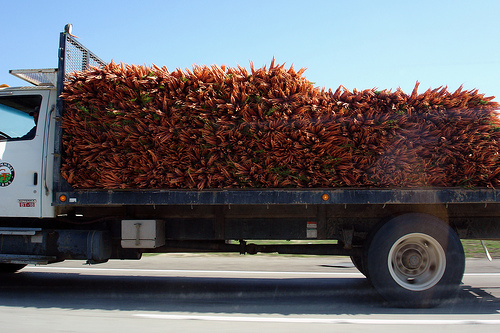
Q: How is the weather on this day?
A: It is cloudless.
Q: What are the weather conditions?
A: It is cloudless.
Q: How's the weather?
A: It is cloudless.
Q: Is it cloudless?
A: Yes, it is cloudless.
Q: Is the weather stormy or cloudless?
A: It is cloudless.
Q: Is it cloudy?
A: No, it is cloudless.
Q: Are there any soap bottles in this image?
A: No, there are no soap bottles.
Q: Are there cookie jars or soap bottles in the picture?
A: No, there are no soap bottles or cookie jars.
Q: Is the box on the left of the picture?
A: Yes, the box is on the left of the image.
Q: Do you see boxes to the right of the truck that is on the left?
A: Yes, there is a box to the right of the truck.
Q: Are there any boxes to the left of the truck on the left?
A: No, the box is to the right of the truck.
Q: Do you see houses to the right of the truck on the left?
A: No, there is a box to the right of the truck.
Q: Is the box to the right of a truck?
A: Yes, the box is to the right of a truck.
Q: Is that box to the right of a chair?
A: No, the box is to the right of a truck.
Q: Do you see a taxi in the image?
A: Yes, there is a taxi.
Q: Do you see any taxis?
A: Yes, there is a taxi.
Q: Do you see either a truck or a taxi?
A: Yes, there is a taxi.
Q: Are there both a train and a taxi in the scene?
A: No, there is a taxi but no trains.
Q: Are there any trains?
A: No, there are no trains.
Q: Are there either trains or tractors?
A: No, there are no trains or tractors.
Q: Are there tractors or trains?
A: No, there are no trains or tractors.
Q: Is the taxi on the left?
A: Yes, the taxi is on the left of the image.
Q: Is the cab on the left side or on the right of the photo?
A: The cab is on the left of the image.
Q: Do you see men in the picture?
A: No, there are no men.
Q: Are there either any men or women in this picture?
A: No, there are no men or women.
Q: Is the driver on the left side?
A: Yes, the driver is on the left of the image.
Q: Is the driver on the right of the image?
A: No, the driver is on the left of the image.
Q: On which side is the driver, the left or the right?
A: The driver is on the left of the image.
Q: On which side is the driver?
A: The driver is on the left of the image.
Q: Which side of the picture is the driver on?
A: The driver is on the left of the image.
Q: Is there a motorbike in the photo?
A: No, there are no motorcycles.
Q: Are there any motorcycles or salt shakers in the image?
A: No, there are no motorcycles or salt shakers.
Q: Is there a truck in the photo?
A: Yes, there is a truck.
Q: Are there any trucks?
A: Yes, there is a truck.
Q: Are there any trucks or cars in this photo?
A: Yes, there is a truck.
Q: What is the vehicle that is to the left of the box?
A: The vehicle is a truck.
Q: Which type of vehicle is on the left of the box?
A: The vehicle is a truck.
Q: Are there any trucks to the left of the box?
A: Yes, there is a truck to the left of the box.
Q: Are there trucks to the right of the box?
A: No, the truck is to the left of the box.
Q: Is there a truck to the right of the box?
A: No, the truck is to the left of the box.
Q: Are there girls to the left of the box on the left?
A: No, there is a truck to the left of the box.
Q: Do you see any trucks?
A: Yes, there is a truck.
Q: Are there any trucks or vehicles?
A: Yes, there is a truck.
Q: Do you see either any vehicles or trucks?
A: Yes, there is a truck.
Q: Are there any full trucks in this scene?
A: Yes, there is a full truck.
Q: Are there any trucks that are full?
A: Yes, there is a truck that is full.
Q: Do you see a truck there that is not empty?
A: Yes, there is an full truck.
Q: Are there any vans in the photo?
A: No, there are no vans.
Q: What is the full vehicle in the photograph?
A: The vehicle is a truck.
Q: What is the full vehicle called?
A: The vehicle is a truck.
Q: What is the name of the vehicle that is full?
A: The vehicle is a truck.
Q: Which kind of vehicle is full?
A: The vehicle is a truck.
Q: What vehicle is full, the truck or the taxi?
A: The truck is full.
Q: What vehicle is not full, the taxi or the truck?
A: The taxi is not full.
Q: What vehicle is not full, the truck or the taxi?
A: The taxi is not full.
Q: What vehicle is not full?
A: The vehicle is a taxi.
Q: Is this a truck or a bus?
A: This is a truck.